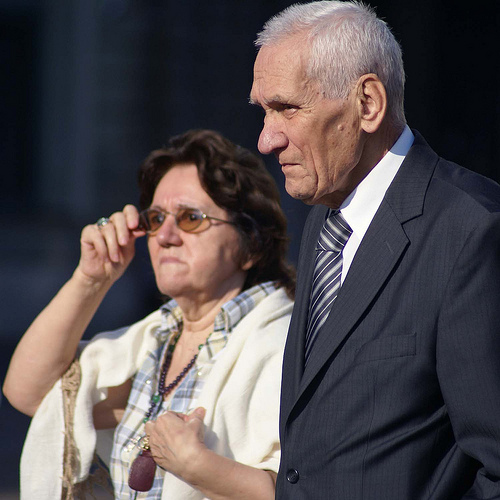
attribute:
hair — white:
[252, 0, 410, 128]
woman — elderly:
[6, 132, 276, 497]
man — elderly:
[251, 3, 496, 498]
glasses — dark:
[118, 197, 207, 227]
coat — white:
[15, 292, 292, 498]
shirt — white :
[302, 124, 417, 317]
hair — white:
[256, 4, 408, 139]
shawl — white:
[26, 294, 344, 462]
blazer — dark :
[269, 133, 499, 498]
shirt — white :
[299, 183, 443, 291]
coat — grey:
[274, 130, 498, 499]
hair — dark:
[141, 117, 237, 197]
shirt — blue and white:
[110, 283, 280, 498]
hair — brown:
[116, 137, 289, 284]